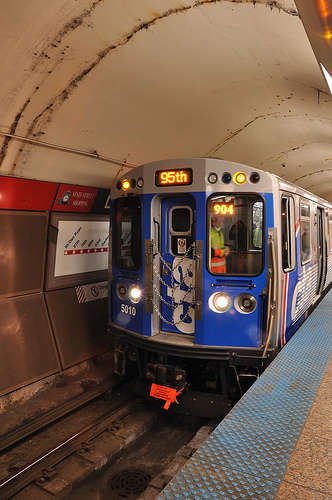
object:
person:
[211, 212, 231, 273]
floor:
[134, 283, 332, 499]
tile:
[155, 292, 332, 499]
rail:
[0, 375, 214, 499]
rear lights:
[123, 169, 246, 193]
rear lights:
[118, 284, 259, 315]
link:
[174, 262, 179, 265]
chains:
[149, 242, 195, 326]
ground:
[269, 128, 286, 137]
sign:
[0, 175, 99, 214]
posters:
[54, 220, 109, 277]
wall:
[0, 175, 110, 398]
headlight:
[208, 291, 230, 314]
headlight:
[130, 287, 141, 299]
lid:
[106, 465, 150, 499]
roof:
[0, 1, 332, 206]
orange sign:
[149, 382, 181, 409]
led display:
[155, 167, 192, 186]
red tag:
[149, 382, 182, 410]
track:
[2, 365, 238, 499]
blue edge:
[154, 290, 331, 499]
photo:
[0, 0, 332, 498]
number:
[121, 303, 136, 315]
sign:
[213, 203, 234, 214]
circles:
[191, 418, 299, 482]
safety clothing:
[211, 225, 231, 273]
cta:
[167, 256, 195, 334]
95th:
[160, 170, 187, 184]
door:
[150, 189, 199, 341]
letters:
[167, 256, 196, 333]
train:
[107, 156, 332, 415]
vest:
[209, 225, 227, 272]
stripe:
[281, 273, 290, 347]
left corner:
[107, 299, 152, 336]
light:
[121, 168, 247, 191]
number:
[160, 170, 188, 183]